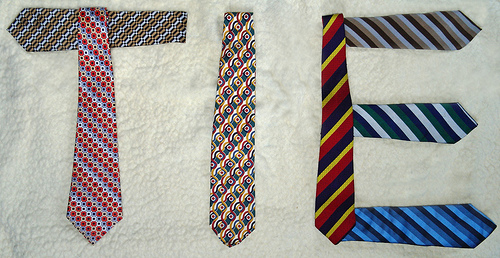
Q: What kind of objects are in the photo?
A: Ties.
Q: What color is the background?
A: White.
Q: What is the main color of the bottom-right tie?
A: Blue.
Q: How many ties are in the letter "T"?
A: Two.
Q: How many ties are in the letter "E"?
A: Four.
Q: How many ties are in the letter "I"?
A: One.